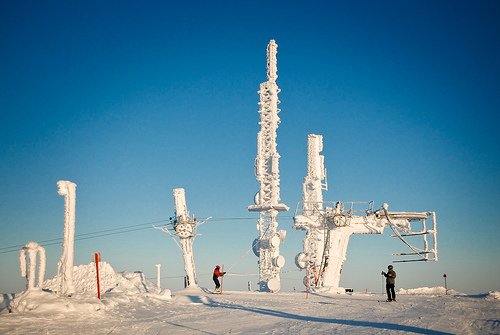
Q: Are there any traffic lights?
A: No, there are no traffic lights.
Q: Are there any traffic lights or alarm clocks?
A: No, there are no traffic lights or alarm clocks.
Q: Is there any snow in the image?
A: Yes, there is snow.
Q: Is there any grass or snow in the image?
A: Yes, there is snow.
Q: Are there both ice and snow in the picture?
A: Yes, there are both snow and ice.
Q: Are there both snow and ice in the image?
A: Yes, there are both snow and ice.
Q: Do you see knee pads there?
A: No, there are no knee pads.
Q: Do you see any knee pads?
A: No, there are no knee pads.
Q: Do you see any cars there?
A: No, there are no cars.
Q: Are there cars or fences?
A: No, there are no cars or fences.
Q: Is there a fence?
A: No, there are no fences.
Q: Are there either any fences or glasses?
A: No, there are no fences or glasses.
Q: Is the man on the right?
A: Yes, the man is on the right of the image.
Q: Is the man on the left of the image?
A: No, the man is on the right of the image.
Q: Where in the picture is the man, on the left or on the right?
A: The man is on the right of the image.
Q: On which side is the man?
A: The man is on the right of the image.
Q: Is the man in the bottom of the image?
A: Yes, the man is in the bottom of the image.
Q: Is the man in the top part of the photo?
A: No, the man is in the bottom of the image.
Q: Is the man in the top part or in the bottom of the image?
A: The man is in the bottom of the image.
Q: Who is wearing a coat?
A: The man is wearing a coat.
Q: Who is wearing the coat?
A: The man is wearing a coat.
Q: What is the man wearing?
A: The man is wearing a coat.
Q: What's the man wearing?
A: The man is wearing a coat.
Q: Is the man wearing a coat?
A: Yes, the man is wearing a coat.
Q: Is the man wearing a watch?
A: No, the man is wearing a coat.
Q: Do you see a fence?
A: No, there are no fences.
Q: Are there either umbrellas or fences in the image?
A: No, there are no fences or umbrellas.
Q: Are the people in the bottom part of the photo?
A: Yes, the people are in the bottom of the image.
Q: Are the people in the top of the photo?
A: No, the people are in the bottom of the image.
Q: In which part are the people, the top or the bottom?
A: The people are in the bottom of the image.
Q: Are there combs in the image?
A: No, there are no combs.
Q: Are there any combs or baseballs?
A: No, there are no combs or baseballs.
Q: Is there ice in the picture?
A: Yes, there is ice.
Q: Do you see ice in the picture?
A: Yes, there is ice.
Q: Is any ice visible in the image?
A: Yes, there is ice.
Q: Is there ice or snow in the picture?
A: Yes, there is ice.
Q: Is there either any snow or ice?
A: Yes, there is ice.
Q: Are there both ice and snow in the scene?
A: Yes, there are both ice and snow.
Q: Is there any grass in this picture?
A: No, there is no grass.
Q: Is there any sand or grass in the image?
A: No, there are no grass or sand.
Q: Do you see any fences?
A: No, there are no fences.